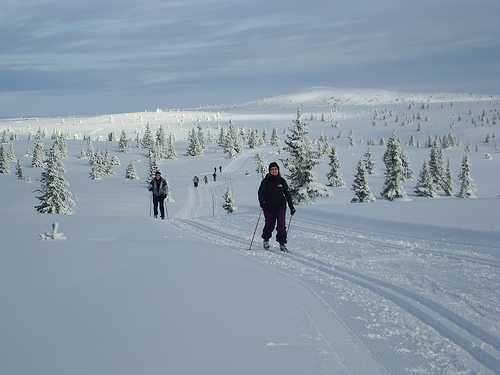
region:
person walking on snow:
[247, 161, 306, 256]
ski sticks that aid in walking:
[247, 203, 301, 249]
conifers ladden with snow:
[347, 139, 477, 199]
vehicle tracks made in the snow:
[334, 236, 499, 371]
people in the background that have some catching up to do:
[191, 163, 228, 188]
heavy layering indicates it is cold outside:
[257, 173, 293, 243]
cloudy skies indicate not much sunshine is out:
[1, 0, 494, 98]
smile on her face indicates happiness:
[268, 162, 281, 177]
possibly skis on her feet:
[262, 239, 294, 258]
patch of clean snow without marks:
[3, 235, 228, 368]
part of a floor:
[341, 241, 373, 284]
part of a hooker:
[243, 226, 275, 283]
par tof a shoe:
[278, 247, 291, 270]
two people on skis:
[47, 110, 478, 359]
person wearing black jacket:
[252, 172, 299, 209]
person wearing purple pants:
[260, 203, 293, 245]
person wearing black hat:
[263, 158, 280, 173]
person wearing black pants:
[145, 189, 170, 216]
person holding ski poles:
[235, 196, 310, 256]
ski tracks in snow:
[300, 240, 498, 369]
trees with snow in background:
[33, 106, 460, 183]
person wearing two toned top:
[147, 178, 171, 198]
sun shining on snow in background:
[15, 85, 239, 150]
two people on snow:
[111, 133, 312, 255]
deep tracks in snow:
[254, 181, 479, 361]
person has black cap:
[261, 160, 283, 174]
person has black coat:
[251, 174, 285, 206]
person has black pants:
[251, 207, 289, 248]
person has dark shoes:
[251, 238, 289, 248]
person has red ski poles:
[250, 201, 291, 233]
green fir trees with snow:
[157, 110, 465, 205]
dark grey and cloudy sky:
[80, 0, 238, 121]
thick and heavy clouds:
[130, 24, 301, 101]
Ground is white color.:
[106, 234, 275, 307]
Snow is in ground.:
[93, 233, 245, 331]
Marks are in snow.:
[313, 241, 464, 371]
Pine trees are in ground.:
[23, 123, 465, 221]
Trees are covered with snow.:
[11, 123, 496, 235]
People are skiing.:
[130, 143, 310, 268]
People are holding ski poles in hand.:
[129, 155, 335, 265]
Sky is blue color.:
[36, 13, 259, 76]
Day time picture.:
[25, 44, 468, 316]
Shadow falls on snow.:
[32, 131, 488, 255]